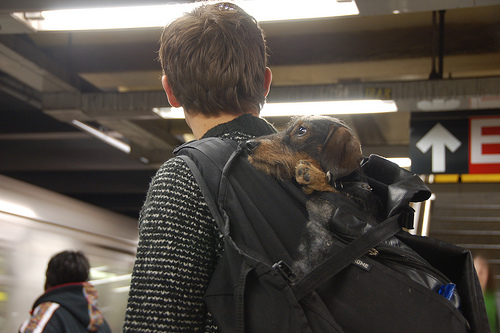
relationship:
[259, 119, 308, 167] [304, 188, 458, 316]
dog in backpack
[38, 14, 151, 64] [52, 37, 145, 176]
light on ceiling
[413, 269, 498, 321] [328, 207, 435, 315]
tag on bookbag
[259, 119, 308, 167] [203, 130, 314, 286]
dog on back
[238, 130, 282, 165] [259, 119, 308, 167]
nose of dog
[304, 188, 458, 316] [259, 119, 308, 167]
backpack has dog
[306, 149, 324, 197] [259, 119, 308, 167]
paw of dog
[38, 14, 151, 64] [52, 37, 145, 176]
light in ceiling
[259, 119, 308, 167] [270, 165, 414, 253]
dog in carrier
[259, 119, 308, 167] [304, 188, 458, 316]
dog on backpack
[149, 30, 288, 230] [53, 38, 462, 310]
boy at airport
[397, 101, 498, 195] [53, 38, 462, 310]
sign at airport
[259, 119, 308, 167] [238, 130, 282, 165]
dog has nose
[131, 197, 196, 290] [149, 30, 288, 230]
sleeve of boy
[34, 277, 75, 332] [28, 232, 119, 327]
jacket on person